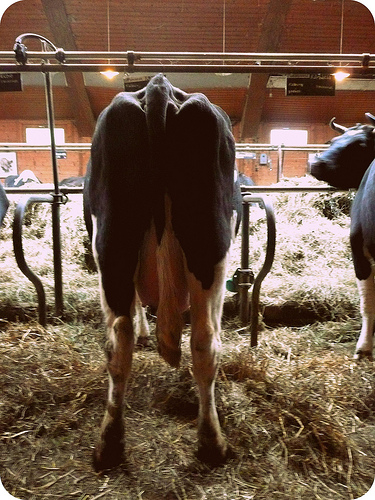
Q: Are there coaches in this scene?
A: No, there are no coaches.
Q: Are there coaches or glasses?
A: No, there are no coaches or glasses.